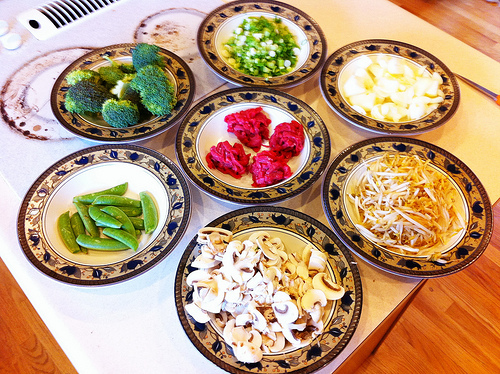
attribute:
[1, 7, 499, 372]
table — normal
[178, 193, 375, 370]
plate — made for dining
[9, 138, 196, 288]
bowl — white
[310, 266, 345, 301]
mushroom — tan, sliced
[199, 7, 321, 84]
dining plate — made for dining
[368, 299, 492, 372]
counter — brown, wooden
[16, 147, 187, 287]
plate — made for dining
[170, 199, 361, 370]
plate — made for dining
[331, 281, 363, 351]
trim — blue 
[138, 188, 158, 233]
snap beans — green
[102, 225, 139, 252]
snap beans — green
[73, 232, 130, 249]
snap beans — green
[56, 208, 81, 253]
snap beans — green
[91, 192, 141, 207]
snap beans — green